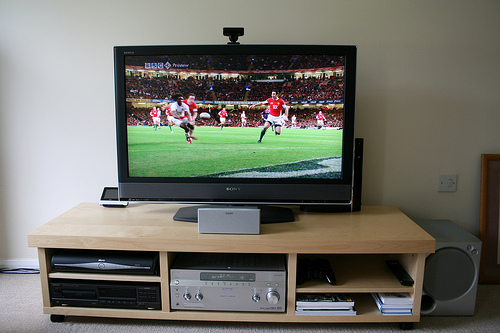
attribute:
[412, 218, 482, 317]
speaker — silver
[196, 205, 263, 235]
speaker — center, aux audio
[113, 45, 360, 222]
television — wide-screen, black, flat screen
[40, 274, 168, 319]
console — black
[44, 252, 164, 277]
box — black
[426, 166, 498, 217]
socket — small, white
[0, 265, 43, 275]
power cords — electric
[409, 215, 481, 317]
speaker box — gray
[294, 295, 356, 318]
cases — plastic, white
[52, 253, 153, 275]
dvd player — shiny, black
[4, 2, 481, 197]
wall — white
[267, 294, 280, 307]
knob — large, silver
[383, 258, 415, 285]
remote — thin, black